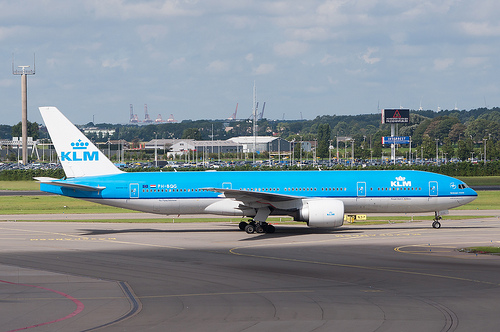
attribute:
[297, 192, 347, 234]
engine — large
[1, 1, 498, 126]
clouds — white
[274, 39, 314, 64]
cloud — white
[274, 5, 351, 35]
cloud — white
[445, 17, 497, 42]
cloud — white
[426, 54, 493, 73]
cloud — white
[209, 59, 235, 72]
cloud — white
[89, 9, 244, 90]
clouds — white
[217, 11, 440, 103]
clouds — white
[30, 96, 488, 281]
line — large, pink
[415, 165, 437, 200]
ground — brown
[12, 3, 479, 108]
sky — cloudy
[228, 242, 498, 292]
line — yellow, large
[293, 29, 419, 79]
clouds — white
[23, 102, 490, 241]
airplane — blue, blue and white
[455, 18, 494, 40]
clouds — white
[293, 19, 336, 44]
clouds — white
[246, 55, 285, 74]
clouds — white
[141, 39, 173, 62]
clouds — white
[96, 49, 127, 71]
clouds — white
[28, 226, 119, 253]
lines — painted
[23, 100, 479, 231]
plane — blue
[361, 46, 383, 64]
cloud — small, white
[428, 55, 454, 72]
cloud — small, white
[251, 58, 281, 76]
cloud — small, white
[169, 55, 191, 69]
cloud — small, white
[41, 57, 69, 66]
cloud — small, white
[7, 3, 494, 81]
clouds — white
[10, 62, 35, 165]
tower — radio control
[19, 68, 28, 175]
pole — tall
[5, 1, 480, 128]
sky — blue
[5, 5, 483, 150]
sky — blue